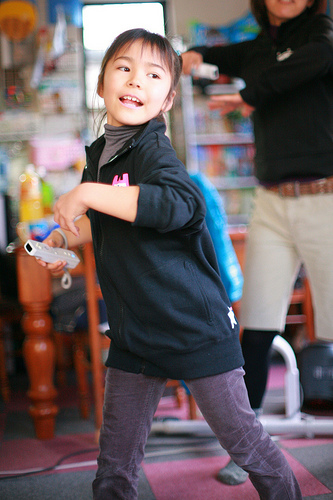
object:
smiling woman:
[31, 24, 304, 499]